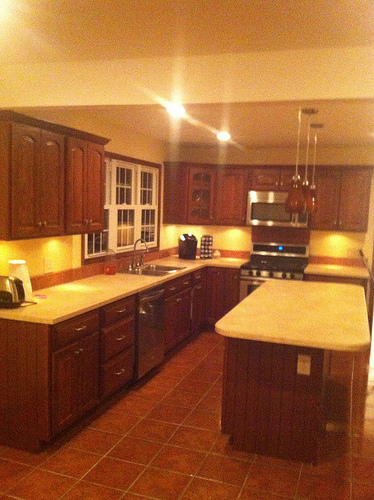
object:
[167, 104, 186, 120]
light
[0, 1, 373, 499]
kitchen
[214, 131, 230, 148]
light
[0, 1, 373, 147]
ceiling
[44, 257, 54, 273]
outlet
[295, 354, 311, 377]
outlet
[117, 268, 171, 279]
sink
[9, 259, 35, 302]
paper towels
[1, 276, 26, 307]
toaster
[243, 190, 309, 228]
microwave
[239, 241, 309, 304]
stove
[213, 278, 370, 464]
island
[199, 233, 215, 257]
keurig coffee holder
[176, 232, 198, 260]
coffee maker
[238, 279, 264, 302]
oven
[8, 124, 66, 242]
cabinet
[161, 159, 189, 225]
cabinet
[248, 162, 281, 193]
cabinet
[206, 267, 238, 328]
cabinet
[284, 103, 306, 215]
light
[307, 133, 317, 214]
light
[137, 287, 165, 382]
dishwasher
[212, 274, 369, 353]
counter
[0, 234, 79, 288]
wall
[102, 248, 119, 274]
bottle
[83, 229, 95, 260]
windows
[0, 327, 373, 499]
floor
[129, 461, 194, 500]
floor tile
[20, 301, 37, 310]
cord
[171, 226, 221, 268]
corner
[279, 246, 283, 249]
clock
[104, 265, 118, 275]
dish soap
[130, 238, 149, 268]
faucet